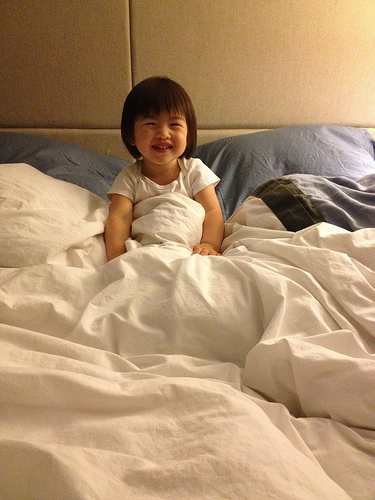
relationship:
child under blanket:
[103, 75, 225, 262] [2, 159, 373, 498]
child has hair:
[103, 75, 225, 262] [121, 73, 198, 119]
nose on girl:
[155, 122, 169, 140] [154, 124, 171, 141]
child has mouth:
[103, 75, 225, 262] [147, 140, 173, 155]